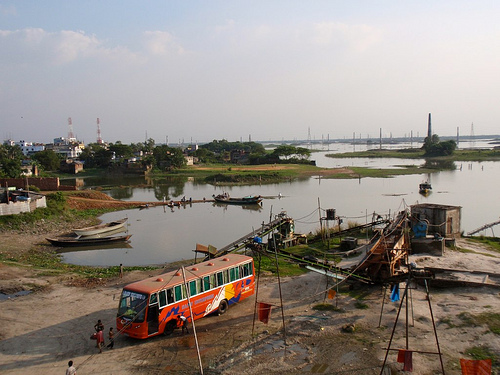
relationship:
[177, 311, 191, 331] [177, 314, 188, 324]
guy has shirt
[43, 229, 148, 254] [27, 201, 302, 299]
boat on shore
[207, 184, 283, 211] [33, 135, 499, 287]
boat in middle of water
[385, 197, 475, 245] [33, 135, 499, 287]
shack on edge of water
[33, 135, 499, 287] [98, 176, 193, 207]
water has reflection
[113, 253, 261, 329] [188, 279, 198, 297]
bus has window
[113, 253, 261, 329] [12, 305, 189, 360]
bus has shadow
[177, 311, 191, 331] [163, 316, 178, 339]
person adjusting tire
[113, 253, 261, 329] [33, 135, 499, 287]
bus parked by water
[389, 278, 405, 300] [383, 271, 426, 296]
flag on wire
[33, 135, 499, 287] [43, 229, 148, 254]
water has boat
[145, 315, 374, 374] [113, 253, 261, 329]
mud puddle near bus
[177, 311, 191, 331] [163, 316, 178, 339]
guy working on tire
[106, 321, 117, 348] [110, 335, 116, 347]
person wearing skirt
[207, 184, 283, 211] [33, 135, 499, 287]
boat in water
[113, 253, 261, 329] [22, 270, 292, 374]
bus in mud